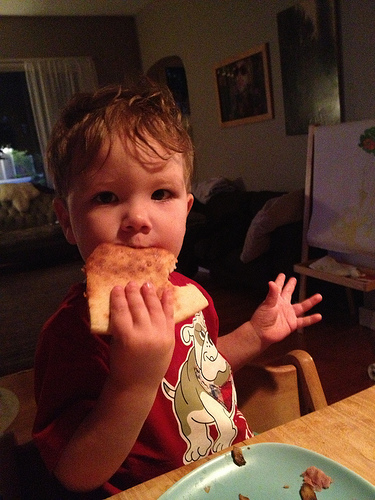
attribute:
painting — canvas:
[271, 3, 373, 138]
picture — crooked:
[210, 42, 276, 123]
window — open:
[0, 65, 50, 179]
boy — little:
[22, 77, 334, 269]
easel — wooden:
[288, 114, 373, 335]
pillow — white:
[238, 187, 302, 269]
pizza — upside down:
[81, 242, 211, 339]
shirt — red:
[30, 265, 249, 491]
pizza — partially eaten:
[51, 221, 234, 354]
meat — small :
[204, 444, 333, 497]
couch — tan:
[0, 181, 79, 265]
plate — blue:
[172, 440, 369, 498]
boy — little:
[49, 93, 344, 448]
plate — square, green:
[152, 437, 373, 498]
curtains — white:
[21, 56, 97, 89]